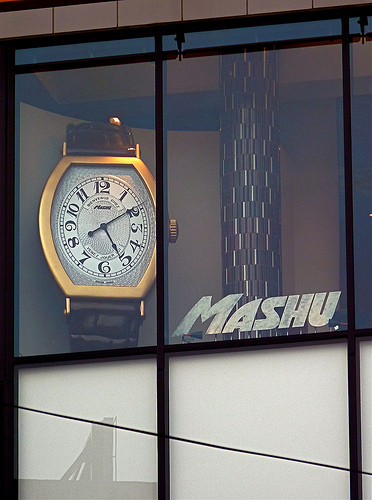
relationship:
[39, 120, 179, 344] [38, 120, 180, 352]
large advertisement watch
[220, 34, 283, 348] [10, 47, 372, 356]
pole inside room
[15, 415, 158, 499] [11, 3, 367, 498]
reflection in window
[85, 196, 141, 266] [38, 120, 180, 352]
hands of watch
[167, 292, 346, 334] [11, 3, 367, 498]
name in window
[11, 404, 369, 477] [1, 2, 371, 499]
wire front building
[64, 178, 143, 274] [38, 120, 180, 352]
numbers on watch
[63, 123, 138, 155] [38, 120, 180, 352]
strap of watch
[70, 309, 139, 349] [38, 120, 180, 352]
strap of watch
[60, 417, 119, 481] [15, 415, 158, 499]
billboard in reflection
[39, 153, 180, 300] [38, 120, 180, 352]
gold brown watch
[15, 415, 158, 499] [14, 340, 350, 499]
reflection lower window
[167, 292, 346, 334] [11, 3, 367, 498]
word mashu window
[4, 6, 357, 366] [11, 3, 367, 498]
frame around window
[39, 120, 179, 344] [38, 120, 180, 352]
big size watch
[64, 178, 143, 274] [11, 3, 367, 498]
clock behind window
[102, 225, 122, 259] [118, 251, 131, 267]
hour hand 5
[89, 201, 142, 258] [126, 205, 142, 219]
hand hand 2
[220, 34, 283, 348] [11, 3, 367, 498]
pole behind window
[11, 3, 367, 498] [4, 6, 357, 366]
window with frame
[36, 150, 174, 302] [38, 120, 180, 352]
clock on watch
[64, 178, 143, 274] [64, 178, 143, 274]
numbers on clock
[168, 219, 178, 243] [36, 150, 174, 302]
knob on right clock